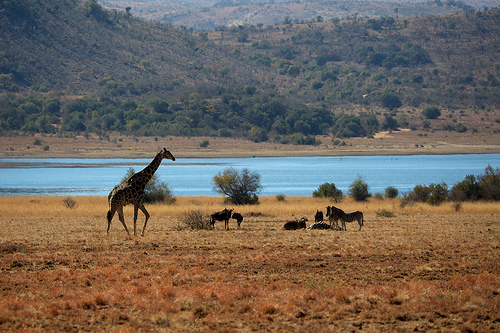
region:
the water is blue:
[303, 156, 410, 171]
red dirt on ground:
[373, 125, 413, 140]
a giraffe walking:
[100, 140, 170, 235]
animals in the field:
[280, 200, 365, 236]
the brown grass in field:
[25, 240, 390, 330]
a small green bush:
[205, 160, 265, 205]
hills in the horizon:
[0, 0, 495, 101]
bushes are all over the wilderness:
[0, 0, 495, 140]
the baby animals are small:
[205, 200, 365, 231]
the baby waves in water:
[260, 156, 315, 186]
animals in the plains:
[94, 139, 399, 245]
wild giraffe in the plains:
[102, 140, 184, 236]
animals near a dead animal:
[276, 199, 377, 236]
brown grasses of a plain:
[34, 257, 486, 300]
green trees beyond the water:
[25, 78, 346, 140]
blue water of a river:
[7, 161, 101, 185]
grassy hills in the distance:
[13, 5, 467, 100]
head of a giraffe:
[157, 142, 177, 162]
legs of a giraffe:
[92, 207, 169, 236]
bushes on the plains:
[212, 165, 266, 209]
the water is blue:
[3, 141, 481, 206]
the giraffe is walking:
[95, 108, 212, 224]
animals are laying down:
[269, 207, 333, 236]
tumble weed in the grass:
[176, 199, 231, 249]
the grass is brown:
[1, 179, 495, 319]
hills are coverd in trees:
[0, 3, 498, 111]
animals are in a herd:
[276, 189, 401, 259]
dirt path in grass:
[359, 113, 409, 145]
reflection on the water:
[4, 174, 109, 206]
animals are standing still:
[325, 196, 375, 233]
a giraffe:
[90, 114, 164, 262]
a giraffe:
[117, 115, 231, 313]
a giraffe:
[118, 132, 215, 243]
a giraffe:
[65, 104, 195, 298]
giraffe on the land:
[99, 120, 179, 242]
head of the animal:
[156, 132, 194, 169]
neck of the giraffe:
[136, 153, 164, 185]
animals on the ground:
[197, 173, 397, 273]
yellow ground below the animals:
[209, 234, 305, 296]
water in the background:
[276, 156, 316, 195]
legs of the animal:
[95, 204, 158, 237]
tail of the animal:
[93, 194, 126, 232]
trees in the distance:
[246, 6, 334, 53]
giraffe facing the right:
[78, 128, 202, 233]